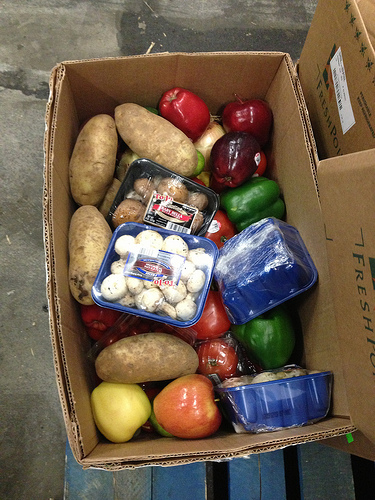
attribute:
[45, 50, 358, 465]
box — cardboard, mixed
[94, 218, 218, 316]
mushrooms — white, brown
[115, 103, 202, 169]
potato — large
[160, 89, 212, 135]
apple — yellow, red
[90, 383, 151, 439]
apple — yellow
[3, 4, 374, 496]
sidewalk — grey, dirty, stained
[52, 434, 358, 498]
table — wooden, blue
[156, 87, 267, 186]
apples — red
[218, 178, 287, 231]
pepper — green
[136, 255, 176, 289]
label — white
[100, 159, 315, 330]
containers — covered, blue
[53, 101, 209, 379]
potatoes — large